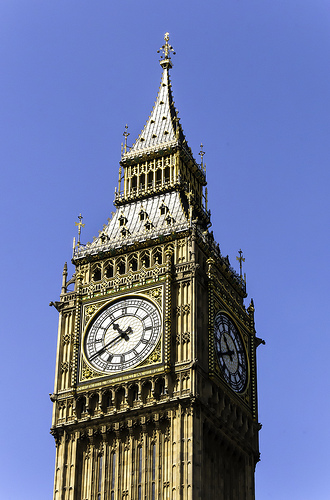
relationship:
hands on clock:
[86, 322, 130, 358] [80, 290, 164, 379]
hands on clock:
[216, 333, 234, 360] [214, 310, 246, 392]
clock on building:
[80, 290, 164, 379] [49, 29, 267, 498]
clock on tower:
[85, 283, 184, 364] [48, 73, 256, 462]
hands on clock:
[86, 324, 132, 362] [28, 244, 285, 415]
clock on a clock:
[80, 290, 164, 379] [210, 309, 249, 392]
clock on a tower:
[80, 290, 164, 379] [46, 26, 268, 498]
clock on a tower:
[210, 304, 252, 397] [46, 26, 268, 498]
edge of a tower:
[173, 415, 201, 488] [31, 29, 314, 498]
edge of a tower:
[163, 238, 224, 407] [46, 26, 268, 498]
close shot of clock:
[26, 28, 300, 493] [80, 290, 164, 379]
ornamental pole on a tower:
[70, 213, 86, 249] [31, 29, 314, 498]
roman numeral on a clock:
[132, 305, 140, 313] [86, 293, 158, 370]